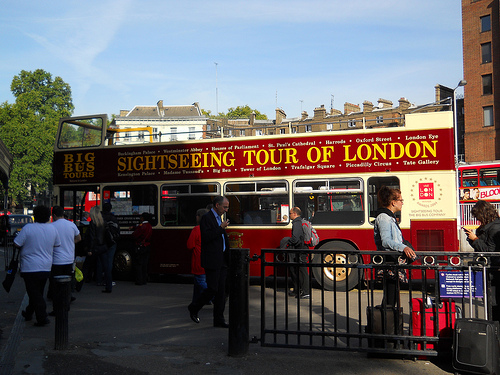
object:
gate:
[257, 248, 500, 356]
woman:
[82, 204, 116, 293]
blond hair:
[89, 205, 104, 227]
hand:
[403, 247, 417, 260]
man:
[48, 206, 82, 318]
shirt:
[212, 208, 225, 251]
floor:
[83, 298, 216, 370]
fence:
[259, 249, 500, 341]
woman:
[373, 185, 416, 308]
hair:
[378, 184, 402, 207]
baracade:
[257, 247, 500, 360]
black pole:
[227, 247, 251, 357]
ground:
[0, 271, 500, 373]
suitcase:
[451, 260, 499, 374]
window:
[478, 40, 495, 66]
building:
[459, 0, 500, 161]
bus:
[47, 113, 460, 291]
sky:
[1, 0, 463, 124]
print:
[62, 152, 95, 178]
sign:
[438, 270, 484, 298]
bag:
[413, 297, 455, 359]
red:
[427, 310, 435, 334]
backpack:
[299, 216, 319, 248]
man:
[279, 206, 319, 300]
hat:
[72, 263, 83, 283]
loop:
[53, 263, 74, 270]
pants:
[289, 244, 308, 292]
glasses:
[398, 199, 405, 201]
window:
[59, 172, 401, 230]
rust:
[337, 254, 346, 265]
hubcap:
[320, 252, 353, 282]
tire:
[310, 239, 365, 291]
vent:
[417, 229, 445, 263]